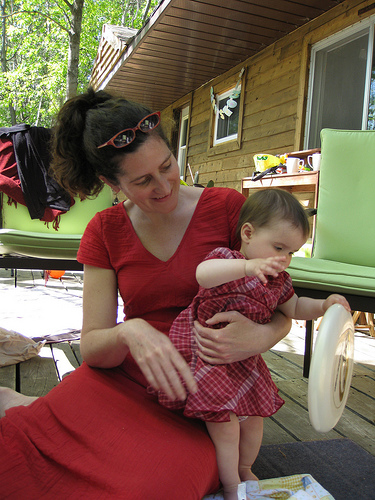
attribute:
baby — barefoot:
[143, 187, 355, 499]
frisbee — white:
[302, 302, 355, 435]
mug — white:
[283, 155, 306, 177]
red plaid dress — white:
[165, 245, 300, 425]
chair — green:
[279, 126, 374, 382]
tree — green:
[0, 1, 87, 124]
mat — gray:
[248, 437, 374, 499]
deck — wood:
[1, 267, 372, 499]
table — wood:
[235, 147, 324, 260]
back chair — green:
[0, 127, 133, 292]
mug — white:
[306, 151, 325, 177]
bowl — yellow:
[248, 151, 284, 180]